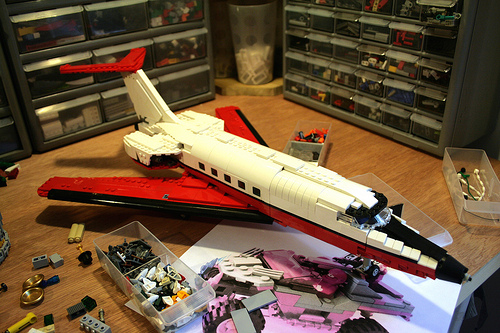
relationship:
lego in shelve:
[300, 127, 338, 148] [259, 6, 482, 131]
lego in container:
[300, 127, 338, 148] [266, 73, 373, 189]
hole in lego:
[78, 316, 89, 322] [300, 127, 338, 148]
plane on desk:
[31, 19, 469, 291] [380, 128, 450, 191]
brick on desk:
[90, 303, 114, 328] [0, 95, 500, 333]